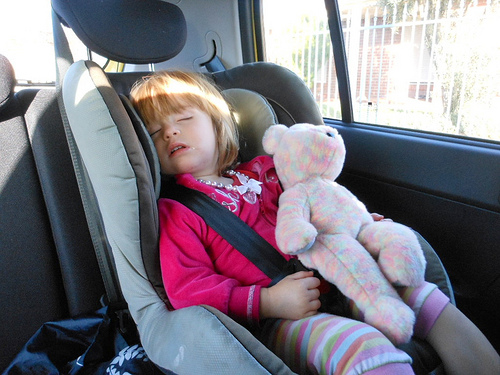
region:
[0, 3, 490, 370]
toddler in a carseat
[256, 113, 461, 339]
toddler holding teddybear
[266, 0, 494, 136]
passenger side window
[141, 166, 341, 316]
hot pink jacket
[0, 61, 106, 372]
back seat of the car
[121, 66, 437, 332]
toddler is asleep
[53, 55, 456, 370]
grey car seat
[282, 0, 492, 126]
fence through the window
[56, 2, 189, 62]
headrest above the carseat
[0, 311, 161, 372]
blue article of clothing in seat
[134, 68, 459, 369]
kid asleep in car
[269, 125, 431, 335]
bear in the car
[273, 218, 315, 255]
paw of the bear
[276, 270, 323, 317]
hand of the kid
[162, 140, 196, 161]
mouth of the kid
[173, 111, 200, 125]
eye of the kid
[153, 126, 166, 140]
eye of the kid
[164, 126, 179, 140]
nose of the kid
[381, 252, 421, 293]
paw of the bear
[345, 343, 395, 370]
color strip on pants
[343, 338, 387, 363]
color strip on pants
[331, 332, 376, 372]
color strip on pants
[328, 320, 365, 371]
color strip on pants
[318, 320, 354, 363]
color strip on pants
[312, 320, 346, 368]
color strip on pants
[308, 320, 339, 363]
color strip on pants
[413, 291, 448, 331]
color strip on pants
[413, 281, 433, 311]
color strip on pants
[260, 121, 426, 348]
a pink and blue teddy bear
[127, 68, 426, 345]
a teddy bear in the little girl's lap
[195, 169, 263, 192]
a pearl necklace around the girl's neck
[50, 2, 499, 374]
a blue and black car seat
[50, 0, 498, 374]
a child sleeping in a car seat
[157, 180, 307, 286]
a black shoulder strap to the carseat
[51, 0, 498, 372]
a girl in a safety seat inside a car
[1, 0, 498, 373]
a girl sleeping inside of a car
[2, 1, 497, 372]
a little girl holding a teddy while sleeping in a car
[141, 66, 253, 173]
the head of a girl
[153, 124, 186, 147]
the nose of a girl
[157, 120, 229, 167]
the mouth of a girl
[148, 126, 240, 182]
the chin of a girl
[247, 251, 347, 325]
the hand of a girl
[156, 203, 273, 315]
the arm of a girl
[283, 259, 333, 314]
the fingers of a girl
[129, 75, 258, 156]
the hair of a girl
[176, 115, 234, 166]
the cheek of a girl